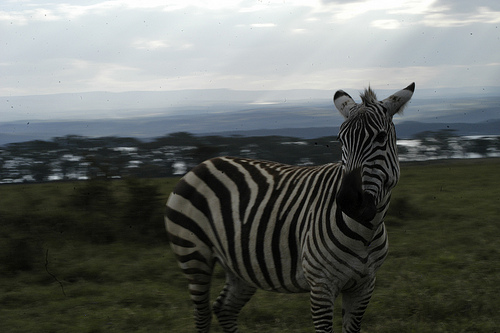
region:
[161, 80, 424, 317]
this is the zebra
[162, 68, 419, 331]
the zebra is motionless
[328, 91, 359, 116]
this is the ear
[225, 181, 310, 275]
this is the belly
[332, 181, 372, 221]
this is the nose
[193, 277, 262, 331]
these are the rare legs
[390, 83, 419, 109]
the ear is long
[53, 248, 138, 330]
this is the grass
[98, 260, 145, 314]
the grass is green in color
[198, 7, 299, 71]
this is the sky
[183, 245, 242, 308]
part of a thigh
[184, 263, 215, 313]
part of a thigh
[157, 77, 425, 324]
this is a zebra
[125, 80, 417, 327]
the zebra is staring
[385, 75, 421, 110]
this is the ear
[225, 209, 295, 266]
the belly is big in size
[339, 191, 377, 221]
this is the mouth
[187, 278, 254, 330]
these are the legs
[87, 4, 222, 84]
this is the sky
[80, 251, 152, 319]
these are the grass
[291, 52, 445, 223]
head of the zebra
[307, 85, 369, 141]
ear of the zebra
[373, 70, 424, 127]
left ear of zebra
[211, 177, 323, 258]
black and white body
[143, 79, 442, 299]
black and white animal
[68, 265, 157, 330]
grass under the animal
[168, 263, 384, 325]
legs of the zebra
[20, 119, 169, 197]
blurry background of photo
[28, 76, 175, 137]
hill in the background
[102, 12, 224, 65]
sky above the water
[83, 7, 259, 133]
this is the sky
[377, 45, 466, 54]
the sky is blue in color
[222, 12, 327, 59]
these are the clouds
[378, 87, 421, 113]
this is the ear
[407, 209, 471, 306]
this is a grass area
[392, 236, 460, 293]
the grass is green in color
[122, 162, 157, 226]
this is a tree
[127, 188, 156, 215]
the leaves are green in color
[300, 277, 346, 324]
this is the leg